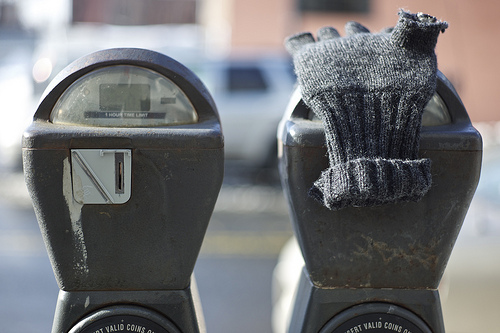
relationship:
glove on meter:
[282, 8, 454, 215] [262, 74, 489, 332]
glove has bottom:
[282, 8, 454, 215] [306, 152, 444, 217]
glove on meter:
[282, 8, 454, 215] [259, 46, 485, 327]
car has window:
[174, 49, 323, 174] [220, 61, 272, 98]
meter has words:
[17, 37, 232, 331] [91, 79, 158, 115]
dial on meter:
[311, 297, 441, 331] [259, 46, 485, 327]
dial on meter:
[319, 300, 434, 333] [274, 56, 476, 331]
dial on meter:
[52, 64, 198, 132] [17, 20, 247, 331]